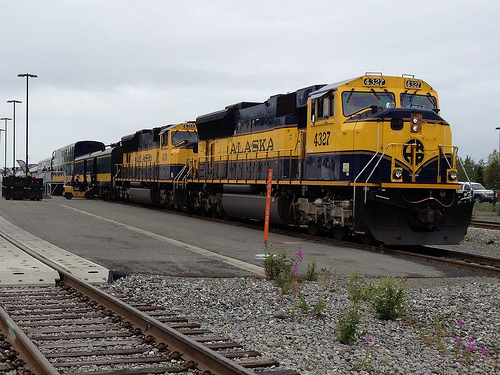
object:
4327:
[313, 130, 331, 146]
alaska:
[230, 137, 277, 154]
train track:
[93, 198, 500, 277]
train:
[0, 70, 476, 246]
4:
[313, 132, 318, 147]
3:
[318, 131, 323, 147]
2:
[321, 131, 327, 145]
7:
[326, 131, 331, 145]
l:
[237, 141, 244, 153]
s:
[251, 139, 261, 152]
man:
[74, 172, 84, 185]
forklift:
[62, 172, 99, 200]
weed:
[333, 303, 362, 345]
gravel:
[0, 219, 500, 374]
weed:
[373, 276, 407, 322]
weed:
[262, 246, 304, 292]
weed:
[313, 296, 326, 315]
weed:
[345, 270, 374, 304]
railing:
[114, 149, 294, 183]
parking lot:
[456, 181, 499, 202]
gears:
[106, 185, 354, 229]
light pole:
[18, 72, 38, 176]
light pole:
[7, 99, 22, 175]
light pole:
[0, 117, 13, 178]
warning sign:
[263, 168, 274, 241]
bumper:
[363, 197, 476, 245]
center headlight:
[411, 125, 420, 132]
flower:
[483, 346, 490, 357]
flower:
[456, 315, 464, 327]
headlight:
[393, 169, 402, 178]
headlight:
[448, 171, 458, 180]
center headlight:
[412, 117, 420, 125]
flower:
[363, 335, 371, 343]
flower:
[292, 263, 300, 276]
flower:
[292, 246, 304, 275]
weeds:
[261, 246, 406, 344]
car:
[455, 181, 493, 202]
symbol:
[401, 140, 424, 167]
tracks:
[0, 200, 498, 374]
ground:
[0, 197, 499, 374]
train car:
[196, 71, 456, 186]